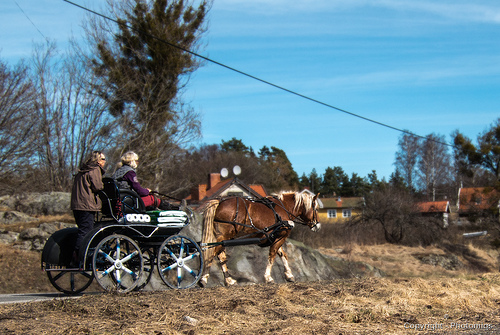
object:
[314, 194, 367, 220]
house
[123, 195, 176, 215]
pants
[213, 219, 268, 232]
threads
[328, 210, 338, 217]
window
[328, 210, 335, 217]
four panes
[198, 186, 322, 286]
horse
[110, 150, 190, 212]
person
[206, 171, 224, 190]
chimney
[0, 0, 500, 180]
clouds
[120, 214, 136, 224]
toilet paper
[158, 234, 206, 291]
wheel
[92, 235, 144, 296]
wheel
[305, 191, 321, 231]
face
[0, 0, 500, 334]
town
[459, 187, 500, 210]
roof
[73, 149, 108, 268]
people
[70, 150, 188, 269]
two people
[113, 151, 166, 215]
driving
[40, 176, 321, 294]
cart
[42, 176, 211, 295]
car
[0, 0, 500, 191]
sky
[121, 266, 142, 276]
spokes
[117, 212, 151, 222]
package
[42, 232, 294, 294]
slowly